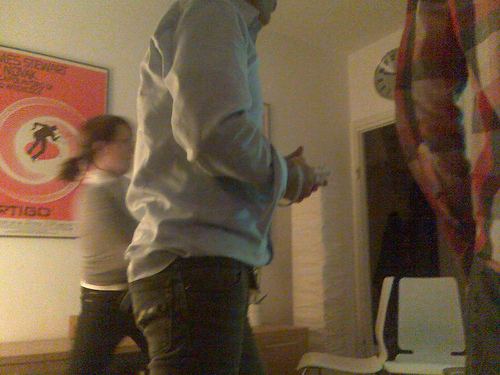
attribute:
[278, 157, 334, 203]
remote — white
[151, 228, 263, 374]
jeans — blue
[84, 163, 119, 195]
collar — white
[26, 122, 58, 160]
silhouette — dark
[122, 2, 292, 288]
sweatshirt — gray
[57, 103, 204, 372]
girl — moving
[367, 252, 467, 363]
chair — white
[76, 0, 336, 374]
people — playing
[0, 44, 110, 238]
poster — red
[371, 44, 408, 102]
clock — silver, black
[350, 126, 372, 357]
door facing — wooden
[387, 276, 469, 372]
chair — white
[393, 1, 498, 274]
shirt — plaid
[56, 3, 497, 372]
people — standing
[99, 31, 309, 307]
shirt — casual, blue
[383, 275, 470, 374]
chairs — white 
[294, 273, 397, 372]
chairs — white 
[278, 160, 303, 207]
strap — white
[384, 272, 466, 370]
chair — plastic, white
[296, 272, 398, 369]
chair — white, plastic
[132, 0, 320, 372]
person — playing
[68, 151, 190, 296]
shirt — plaid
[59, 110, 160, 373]
woman — blurry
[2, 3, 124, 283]
wall — white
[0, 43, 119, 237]
picture — red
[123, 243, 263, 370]
jeans — blue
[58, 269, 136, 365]
jeans — blue